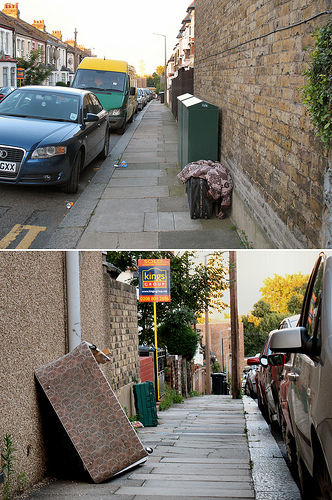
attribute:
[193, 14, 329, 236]
building — brick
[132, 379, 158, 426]
bin — green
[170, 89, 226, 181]
bins — green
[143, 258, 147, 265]
letter —  yellow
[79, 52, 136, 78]
yellow letter —  yellow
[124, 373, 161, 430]
box —  green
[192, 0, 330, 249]
wall — brick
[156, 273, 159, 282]
yellow letter —  yellow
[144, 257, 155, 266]
letter —  yellow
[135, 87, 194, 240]
pavement —  tile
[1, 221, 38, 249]
paint — yellow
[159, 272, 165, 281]
letter —  yellow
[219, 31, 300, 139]
wall — brick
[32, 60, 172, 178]
cars — parked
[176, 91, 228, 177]
garbage bin —  black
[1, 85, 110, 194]
car —  blue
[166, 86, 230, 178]
bins — green